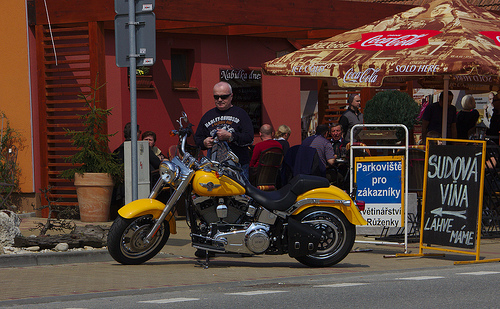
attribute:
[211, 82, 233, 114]
face — has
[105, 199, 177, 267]
wheel — of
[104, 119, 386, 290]
motorcycle — yellow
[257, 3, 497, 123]
umbrella — Sepia color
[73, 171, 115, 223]
plant pot — on the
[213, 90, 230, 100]
sunglasses — black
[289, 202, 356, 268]
tire — inflated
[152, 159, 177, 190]
headlight — infront of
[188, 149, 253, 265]
pants — blue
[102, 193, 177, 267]
tire — round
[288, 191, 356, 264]
wheel — in back of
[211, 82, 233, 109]
head — of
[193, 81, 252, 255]
man — has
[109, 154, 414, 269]
motorcycle — has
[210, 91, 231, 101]
sunglasses — black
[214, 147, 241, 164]
rearview mirror — on side of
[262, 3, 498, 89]
tent — has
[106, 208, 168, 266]
tire — black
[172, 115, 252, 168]
handalbars — on the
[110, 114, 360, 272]
bike — on the, has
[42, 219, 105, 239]
ground — has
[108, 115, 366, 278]
motorcycle — has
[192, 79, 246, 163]
man — has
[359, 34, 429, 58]
logo — on